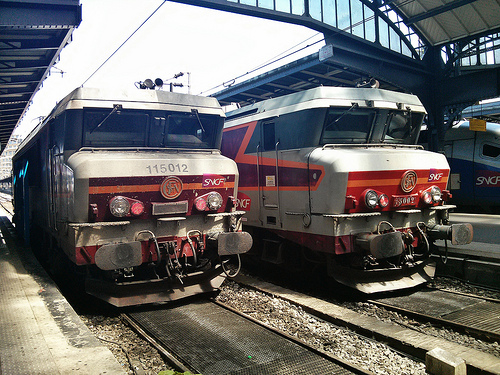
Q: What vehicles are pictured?
A: Trains.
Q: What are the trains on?
A: Tracks.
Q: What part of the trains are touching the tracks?
A: Wheels.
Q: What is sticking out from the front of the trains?
A: Bumbers.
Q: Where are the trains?
A: Train station.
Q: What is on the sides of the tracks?
A: Gravel.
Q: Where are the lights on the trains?
A: Front.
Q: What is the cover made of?
A: Glass.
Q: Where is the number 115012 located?
A: On the front of the train.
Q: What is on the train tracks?
A: A metal rail.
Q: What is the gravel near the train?
A: A track ballast.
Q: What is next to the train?
A: A train platform.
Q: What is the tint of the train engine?
A: Red and white.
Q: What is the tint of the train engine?
A: Red and white.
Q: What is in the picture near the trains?
A: Train tracks.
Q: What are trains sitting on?
A: Tracks.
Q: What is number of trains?
A: Two.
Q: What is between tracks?
A: Gravel.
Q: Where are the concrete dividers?
A: Between train tracks.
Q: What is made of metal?
A: Overhangs.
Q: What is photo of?
A: Two trains in a station.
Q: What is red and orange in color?
A: Two trains.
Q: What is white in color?
A: Roof of trains.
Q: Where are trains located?
A: Train station.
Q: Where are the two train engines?
A: Next to each other.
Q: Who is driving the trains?
A: The engineers.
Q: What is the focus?
A: Trains in station.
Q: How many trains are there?
A: 3.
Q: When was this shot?
A: Daytime.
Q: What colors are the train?
A: Red white orange blue.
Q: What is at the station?
A: Trains.